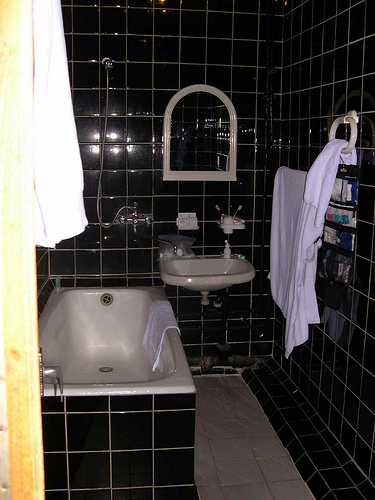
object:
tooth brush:
[214, 205, 224, 220]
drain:
[99, 365, 114, 374]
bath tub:
[35, 288, 176, 390]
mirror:
[170, 90, 231, 173]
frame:
[162, 82, 240, 182]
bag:
[158, 234, 197, 259]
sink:
[164, 256, 250, 278]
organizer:
[318, 164, 354, 297]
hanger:
[325, 112, 360, 154]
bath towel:
[272, 138, 358, 357]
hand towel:
[301, 139, 364, 225]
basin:
[159, 256, 255, 305]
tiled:
[65, 5, 286, 95]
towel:
[267, 165, 313, 353]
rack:
[274, 164, 306, 180]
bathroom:
[0, 0, 375, 500]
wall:
[63, 1, 278, 372]